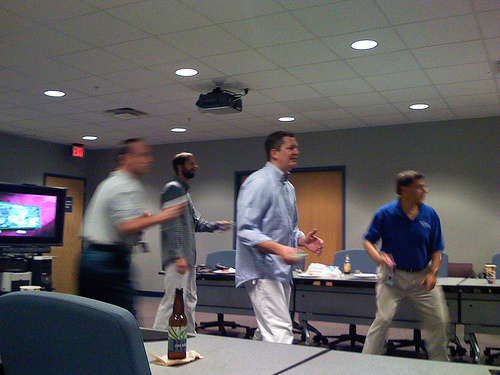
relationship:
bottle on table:
[167, 287, 188, 359] [138, 328, 495, 373]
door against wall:
[229, 161, 350, 271] [78, 108, 498, 284]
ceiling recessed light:
[6, 4, 484, 151] [349, 38, 376, 51]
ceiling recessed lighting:
[6, 4, 484, 151] [407, 94, 430, 119]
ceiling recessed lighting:
[6, 4, 484, 151] [270, 110, 300, 127]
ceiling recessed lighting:
[6, 4, 484, 151] [24, 86, 69, 103]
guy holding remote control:
[361, 169, 451, 361] [383, 266, 395, 286]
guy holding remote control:
[234, 129, 324, 344] [295, 248, 305, 263]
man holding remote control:
[151, 151, 234, 333] [219, 217, 234, 229]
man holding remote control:
[72, 137, 189, 325] [156, 190, 191, 205]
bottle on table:
[160, 285, 192, 362] [138, 320, 498, 373]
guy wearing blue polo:
[361, 169, 451, 361] [361, 197, 446, 276]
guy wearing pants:
[236, 126, 332, 344] [241, 261, 309, 339]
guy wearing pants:
[368, 162, 460, 337] [364, 259, 454, 356]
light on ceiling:
[349, 38, 376, 51] [2, 4, 494, 136]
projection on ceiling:
[195, 86, 251, 114] [35, 15, 498, 96]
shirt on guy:
[361, 198, 447, 275] [361, 169, 451, 361]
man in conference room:
[72, 137, 189, 325] [0, 0, 500, 375]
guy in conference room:
[234, 129, 324, 344] [0, 0, 500, 375]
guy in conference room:
[361, 169, 451, 361] [0, 0, 500, 375]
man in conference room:
[150, 131, 228, 347] [0, 0, 500, 375]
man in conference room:
[90, 135, 159, 336] [0, 0, 500, 375]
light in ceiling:
[344, 30, 377, 56] [6, 4, 484, 151]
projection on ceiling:
[195, 86, 251, 114] [6, 4, 484, 151]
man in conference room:
[72, 137, 189, 325] [28, 95, 498, 118]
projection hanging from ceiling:
[195, 86, 251, 114] [6, 4, 484, 151]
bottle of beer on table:
[167, 287, 188, 359] [163, 324, 449, 374]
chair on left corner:
[1, 291, 151, 373] [1, 274, 155, 374]